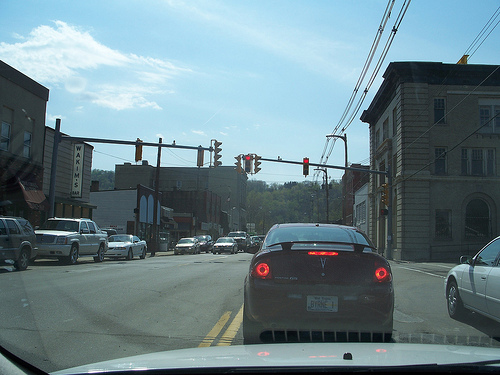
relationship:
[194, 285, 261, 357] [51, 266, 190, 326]
line in road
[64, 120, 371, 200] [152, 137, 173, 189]
lights on bars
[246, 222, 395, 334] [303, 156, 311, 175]
car at light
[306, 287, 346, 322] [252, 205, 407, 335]
license plate of black car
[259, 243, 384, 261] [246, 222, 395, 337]
spoiler of car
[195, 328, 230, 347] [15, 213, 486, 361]
lines on street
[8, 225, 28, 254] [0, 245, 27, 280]
truck on curb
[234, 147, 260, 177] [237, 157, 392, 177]
signals on pole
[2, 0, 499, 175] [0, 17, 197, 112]
sky with thin clouds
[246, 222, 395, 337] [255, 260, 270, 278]
car has tail light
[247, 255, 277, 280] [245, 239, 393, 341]
light on back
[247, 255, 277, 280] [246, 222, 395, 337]
light on car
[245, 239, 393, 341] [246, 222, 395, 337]
back of car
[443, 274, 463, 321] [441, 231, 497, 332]
tire on car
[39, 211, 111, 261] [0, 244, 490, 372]
truck on side of road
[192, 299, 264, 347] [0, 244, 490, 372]
lines on road